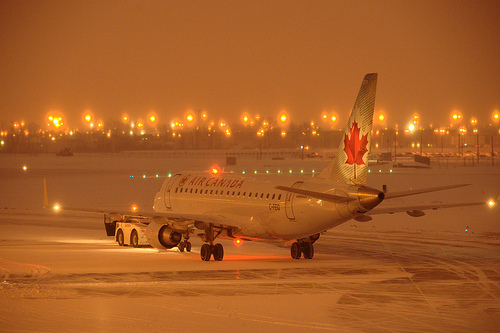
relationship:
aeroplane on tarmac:
[144, 72, 484, 261] [7, 205, 478, 324]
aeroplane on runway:
[144, 72, 484, 261] [13, 160, 482, 310]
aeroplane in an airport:
[64, 69, 485, 262] [10, 104, 498, 329]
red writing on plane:
[181, 166, 245, 206] [115, 69, 486, 296]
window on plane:
[172, 186, 283, 201] [130, 153, 403, 268]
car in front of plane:
[96, 211, 167, 251] [63, 73, 487, 258]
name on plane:
[181, 175, 246, 188] [63, 73, 487, 258]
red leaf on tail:
[340, 121, 370, 184] [333, 70, 378, 185]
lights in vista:
[103, 100, 258, 140] [5, 106, 495, 164]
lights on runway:
[149, 160, 316, 175] [7, 239, 487, 331]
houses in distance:
[121, 110, 243, 144] [0, 99, 499, 169]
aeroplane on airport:
[144, 72, 484, 261] [0, 104, 500, 333]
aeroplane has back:
[144, 72, 484, 261] [282, 67, 402, 261]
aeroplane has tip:
[144, 72, 484, 261] [358, 183, 383, 207]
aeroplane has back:
[144, 72, 484, 261] [280, 77, 381, 259]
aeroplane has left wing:
[144, 72, 484, 261] [359, 196, 494, 221]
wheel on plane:
[290, 241, 315, 260] [127, 68, 493, 276]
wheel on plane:
[287, 240, 303, 260] [127, 68, 493, 276]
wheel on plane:
[200, 243, 225, 261] [127, 68, 493, 276]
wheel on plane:
[197, 242, 212, 261] [127, 68, 493, 276]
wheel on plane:
[182, 240, 192, 251] [127, 68, 493, 276]